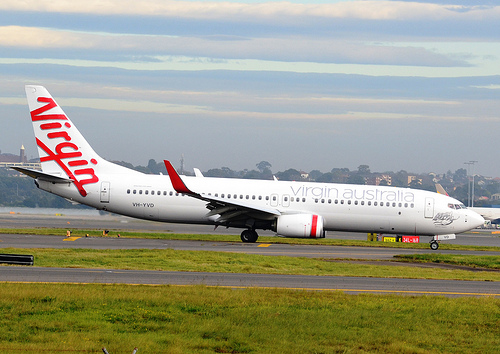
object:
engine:
[271, 213, 324, 238]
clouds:
[0, 0, 500, 131]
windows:
[448, 202, 468, 209]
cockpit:
[442, 195, 472, 217]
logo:
[30, 96, 99, 198]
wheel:
[430, 242, 439, 250]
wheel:
[241, 230, 259, 243]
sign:
[383, 236, 401, 242]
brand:
[289, 185, 416, 202]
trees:
[3, 175, 26, 208]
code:
[133, 202, 154, 207]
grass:
[397, 253, 499, 271]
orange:
[402, 235, 420, 243]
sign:
[402, 236, 420, 243]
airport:
[2, 189, 499, 312]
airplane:
[5, 83, 487, 245]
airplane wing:
[163, 159, 280, 218]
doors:
[100, 182, 110, 203]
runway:
[0, 229, 500, 295]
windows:
[126, 189, 420, 210]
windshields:
[448, 203, 469, 209]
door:
[425, 197, 434, 217]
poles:
[466, 161, 475, 208]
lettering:
[30, 95, 100, 198]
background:
[4, 159, 498, 198]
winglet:
[163, 160, 193, 194]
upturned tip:
[163, 159, 193, 194]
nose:
[464, 208, 486, 232]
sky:
[0, 3, 499, 182]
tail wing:
[24, 85, 146, 178]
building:
[0, 150, 41, 171]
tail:
[25, 84, 142, 179]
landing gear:
[430, 236, 439, 250]